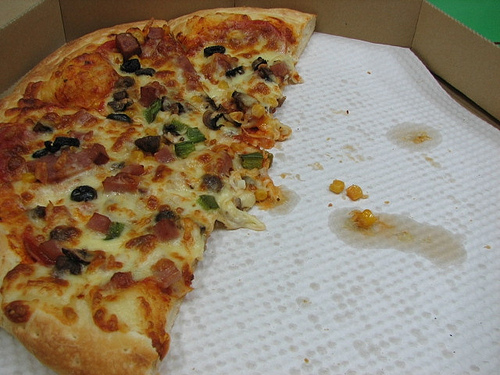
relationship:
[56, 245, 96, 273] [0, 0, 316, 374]
mushroom on pizza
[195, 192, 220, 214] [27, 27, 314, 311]
green pepper on pizza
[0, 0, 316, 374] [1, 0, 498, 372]
pizza in box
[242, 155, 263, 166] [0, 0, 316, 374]
diced greenpepper on pizza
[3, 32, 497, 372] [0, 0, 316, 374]
packaging under pizza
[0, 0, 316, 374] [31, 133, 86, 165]
pizza with olives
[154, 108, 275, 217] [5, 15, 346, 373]
peppers on pizza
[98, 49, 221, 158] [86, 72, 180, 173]
kernals on pizza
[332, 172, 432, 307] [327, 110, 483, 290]
grease stains from pizza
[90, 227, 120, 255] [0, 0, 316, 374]
cheese on pizza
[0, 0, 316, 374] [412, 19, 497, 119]
pizza in box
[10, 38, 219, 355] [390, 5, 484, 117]
pizza in box